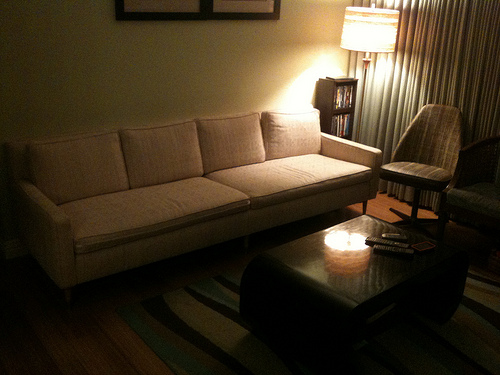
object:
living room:
[1, 1, 498, 374]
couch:
[4, 103, 382, 301]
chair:
[379, 101, 464, 237]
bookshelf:
[315, 75, 357, 144]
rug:
[114, 264, 498, 374]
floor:
[1, 189, 499, 374]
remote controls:
[366, 243, 417, 257]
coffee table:
[238, 213, 467, 357]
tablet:
[412, 240, 434, 253]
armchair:
[435, 133, 499, 242]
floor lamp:
[338, 5, 401, 143]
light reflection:
[323, 228, 374, 276]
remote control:
[364, 234, 409, 249]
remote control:
[382, 231, 408, 241]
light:
[259, 47, 440, 221]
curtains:
[345, 0, 499, 221]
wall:
[1, 1, 349, 134]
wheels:
[387, 205, 395, 211]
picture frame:
[112, 0, 281, 20]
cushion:
[26, 129, 129, 206]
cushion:
[121, 118, 205, 187]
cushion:
[197, 111, 266, 174]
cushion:
[260, 106, 320, 160]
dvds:
[331, 84, 340, 110]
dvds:
[347, 114, 351, 137]